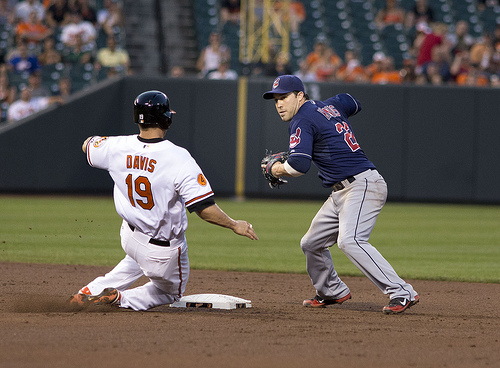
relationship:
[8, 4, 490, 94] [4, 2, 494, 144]
spectators in stands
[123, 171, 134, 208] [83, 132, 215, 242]
number on jersey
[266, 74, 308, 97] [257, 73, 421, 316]
cap on baseball player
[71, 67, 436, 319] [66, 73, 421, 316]
action in action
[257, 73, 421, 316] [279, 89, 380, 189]
baseball player wearing shirt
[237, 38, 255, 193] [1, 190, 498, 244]
pole in field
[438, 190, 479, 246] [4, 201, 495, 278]
grass on outfield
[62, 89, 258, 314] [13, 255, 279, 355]
baseball player on second base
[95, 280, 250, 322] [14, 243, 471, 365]
shadow on infield dirt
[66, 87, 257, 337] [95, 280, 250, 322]
baseball player projects shadow